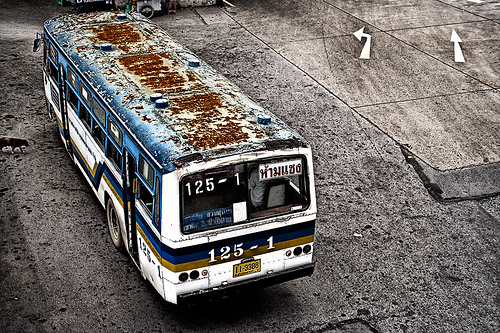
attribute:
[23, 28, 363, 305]
bus — rusty, blue, white, old, parked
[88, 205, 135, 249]
wheel — black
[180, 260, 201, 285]
lights — off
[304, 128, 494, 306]
road — concrete, dirty, grey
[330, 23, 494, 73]
arrows — white, pointing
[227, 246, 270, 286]
license — yellow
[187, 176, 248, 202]
numbers — white, 125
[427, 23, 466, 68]
arrow — ahead, white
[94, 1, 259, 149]
leaves — brown